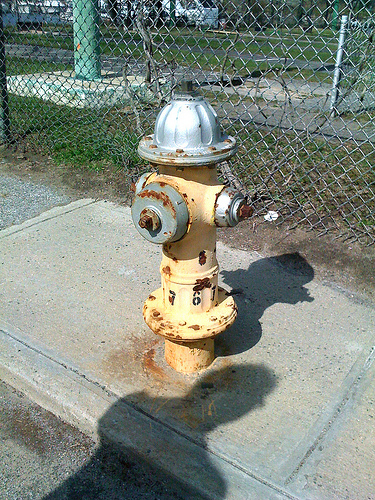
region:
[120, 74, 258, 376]
rusty old fire hydrant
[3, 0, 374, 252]
metal chain link fence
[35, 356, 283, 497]
shadow of a person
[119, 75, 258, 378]
fire hydrant is silver and yellow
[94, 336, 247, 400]
rust stains on the sidewalk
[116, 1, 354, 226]
vines and branches behind the fence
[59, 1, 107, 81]
green pole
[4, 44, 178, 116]
concrete base for the pole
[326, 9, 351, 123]
silver metal fence post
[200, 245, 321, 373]
shadow of the fire hydrant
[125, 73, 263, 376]
a rusty yellow fire hydrant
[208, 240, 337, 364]
the shadow of the fire hydrant cast on the sidewalk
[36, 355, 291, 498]
the shadow of a person cast on the sidewalk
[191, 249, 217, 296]
rust on the fire hydrant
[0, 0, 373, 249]
a chain link fence behind the sidewalk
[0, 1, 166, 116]
a green pole mounted in a concrete slab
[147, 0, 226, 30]
a small white building in the distance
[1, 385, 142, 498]
gravel on the side of the road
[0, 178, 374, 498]
a sidewalk with gravel strewn on it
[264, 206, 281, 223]
a piece of trash on the ground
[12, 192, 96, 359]
a gray concrete side walk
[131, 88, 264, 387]
a fire hydrant on a side walk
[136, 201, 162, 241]
A rusty bolt on a fire hydrant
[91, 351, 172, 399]
rust on the concrete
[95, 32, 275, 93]
a silver metal fence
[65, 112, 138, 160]
green grass on the other side of fence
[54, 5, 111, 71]
a green metal pole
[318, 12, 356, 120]
a silver metal pole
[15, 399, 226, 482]
the curb of the side walk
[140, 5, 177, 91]
a vine on the fence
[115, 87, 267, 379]
small yellow fire hydrant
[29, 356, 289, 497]
shadow on the ground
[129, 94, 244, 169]
top of the hydrant is silver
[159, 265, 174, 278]
rust on the hydrant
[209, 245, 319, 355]
shadow from the fire hydrant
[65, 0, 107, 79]
thick green pole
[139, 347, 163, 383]
rust marks on the sidewalk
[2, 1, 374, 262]
tall chain link fence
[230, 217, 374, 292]
brown dirt along the fence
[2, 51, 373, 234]
green grass on the ground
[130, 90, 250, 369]
a yellow fire hydrant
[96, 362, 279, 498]
the shadow of a person on the sidewalk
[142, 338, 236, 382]
a rust ring on the sidewalk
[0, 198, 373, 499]
a concrete sidewalk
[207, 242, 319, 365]
the shadow of a fire hydrant on the sidewalk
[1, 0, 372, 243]
a chain link fence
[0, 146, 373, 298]
dirt collecting at the base of a chain link fence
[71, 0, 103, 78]
a large green post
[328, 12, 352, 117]
a metal post behind a fence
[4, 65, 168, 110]
a square concrete slab